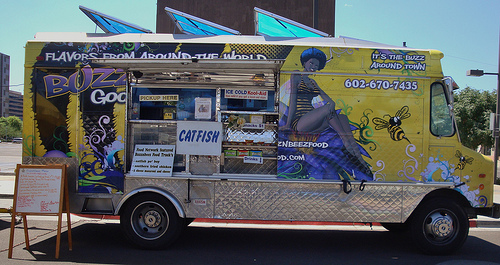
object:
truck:
[22, 4, 497, 254]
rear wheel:
[119, 193, 185, 250]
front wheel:
[405, 196, 471, 256]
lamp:
[466, 69, 484, 77]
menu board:
[7, 164, 72, 260]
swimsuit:
[290, 75, 321, 133]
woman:
[278, 47, 372, 178]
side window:
[128, 86, 278, 120]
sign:
[176, 120, 222, 155]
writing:
[179, 129, 220, 143]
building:
[156, 0, 336, 38]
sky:
[1, 0, 500, 96]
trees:
[432, 84, 500, 155]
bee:
[372, 105, 412, 144]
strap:
[186, 178, 192, 203]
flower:
[277, 108, 373, 184]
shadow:
[23, 222, 500, 265]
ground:
[0, 142, 500, 265]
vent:
[79, 5, 332, 40]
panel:
[125, 173, 455, 223]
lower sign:
[129, 144, 176, 176]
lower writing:
[135, 148, 174, 158]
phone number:
[344, 78, 419, 91]